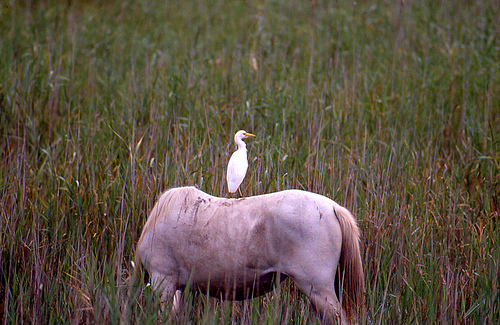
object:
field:
[3, 5, 498, 320]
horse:
[131, 185, 368, 324]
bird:
[225, 129, 257, 197]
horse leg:
[293, 269, 353, 322]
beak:
[243, 132, 256, 137]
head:
[235, 129, 257, 138]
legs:
[148, 275, 178, 325]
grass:
[2, 2, 500, 322]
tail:
[332, 200, 374, 318]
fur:
[331, 204, 370, 315]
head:
[123, 248, 146, 318]